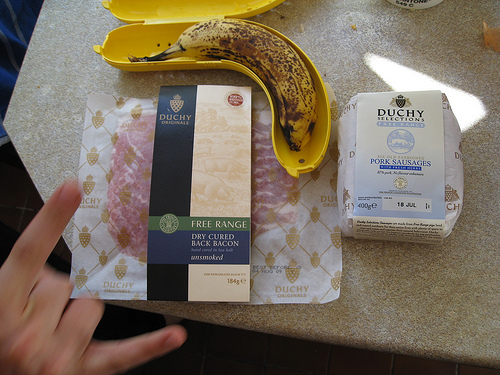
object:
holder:
[124, 39, 190, 65]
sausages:
[391, 158, 433, 167]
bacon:
[109, 111, 297, 264]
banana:
[126, 17, 320, 153]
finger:
[0, 177, 87, 339]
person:
[0, 174, 190, 373]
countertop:
[0, 0, 500, 369]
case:
[91, 16, 333, 179]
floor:
[0, 0, 47, 375]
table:
[1, 0, 500, 369]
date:
[396, 201, 431, 210]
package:
[332, 87, 470, 243]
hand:
[0, 174, 191, 374]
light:
[358, 48, 491, 135]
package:
[64, 80, 346, 307]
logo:
[158, 213, 181, 236]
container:
[91, 0, 332, 180]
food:
[98, 17, 469, 265]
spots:
[245, 48, 262, 58]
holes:
[156, 43, 161, 48]